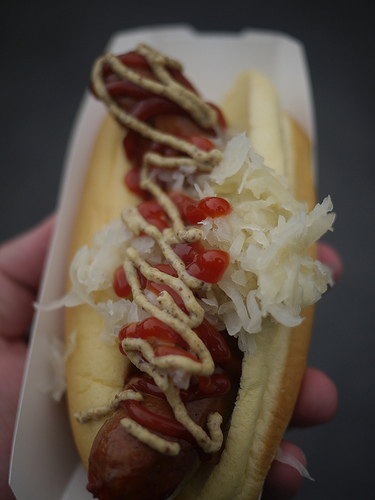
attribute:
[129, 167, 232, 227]
ketchup — red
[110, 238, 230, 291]
ketchup — red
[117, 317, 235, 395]
ketchup — red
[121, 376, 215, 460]
ketchup — red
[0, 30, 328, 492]
container — white, cardboard, food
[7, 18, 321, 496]
paper — white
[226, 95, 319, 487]
bun — fluffy, hotdog bun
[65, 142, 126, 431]
bun — hotdog bun, fluffy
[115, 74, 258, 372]
condiments — red and white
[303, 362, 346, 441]
finger — pinky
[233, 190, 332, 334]
saurkraut — some, shredded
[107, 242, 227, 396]
mustard — yellow, spicy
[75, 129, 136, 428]
hotdog bun — fresh 